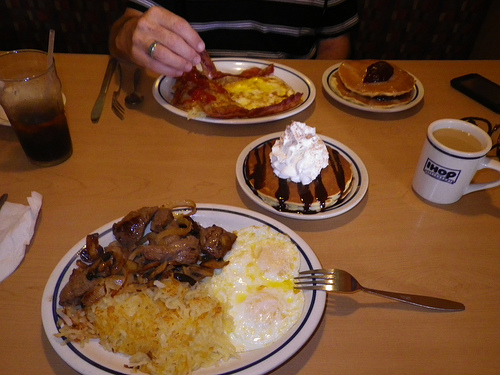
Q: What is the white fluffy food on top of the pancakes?
A: Whipped cream.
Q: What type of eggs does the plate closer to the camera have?
A: Over easy.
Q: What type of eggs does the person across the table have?
A: Scrambled.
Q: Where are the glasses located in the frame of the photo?
A: Upper right side behind the coffee.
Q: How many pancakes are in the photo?
A: Four.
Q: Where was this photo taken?
A: Ihop.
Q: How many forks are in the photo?
A: Two.